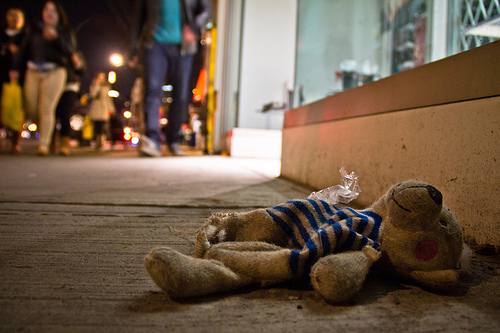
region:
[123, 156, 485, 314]
Teddy bear on the sidewalk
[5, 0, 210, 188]
People walking on the sidewalk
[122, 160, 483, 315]
Ripped teddy bear missing its stuffing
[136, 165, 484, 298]
Teddy bear with blue stripes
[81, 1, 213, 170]
Person wearing blue jeans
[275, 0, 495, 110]
Store front grass window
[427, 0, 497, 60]
Gate across door to a store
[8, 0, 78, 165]
Woman wearing tan colored pants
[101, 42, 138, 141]
Street lights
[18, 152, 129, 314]
Rough concrete sidewalk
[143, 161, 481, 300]
torn apart stuffed bear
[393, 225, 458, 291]
red cheek on stuffed bear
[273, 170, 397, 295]
blue and white shirt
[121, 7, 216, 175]
man walking down the street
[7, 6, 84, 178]
woman carrying a yellow bag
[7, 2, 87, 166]
woman walking down the street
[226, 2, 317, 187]
opening to store entrance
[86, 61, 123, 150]
woman talking on cellphone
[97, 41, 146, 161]
city lights in the distance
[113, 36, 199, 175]
man wearing blue denims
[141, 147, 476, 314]
the teddy bear is flat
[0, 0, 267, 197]
people are walking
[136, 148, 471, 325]
the teddy bear is wearing a blue shirt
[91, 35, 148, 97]
a light is shining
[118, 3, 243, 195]
the person is wearing blue jeans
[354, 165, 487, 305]
the teddy bear has a pink cheek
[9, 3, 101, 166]
the woman is wearing tan pants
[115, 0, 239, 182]
the person is wearing a blue shirt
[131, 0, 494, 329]
a glass window above the bear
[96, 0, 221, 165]
the person is wearing a black jacket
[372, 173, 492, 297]
the head of a teddy bear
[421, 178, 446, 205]
the nose of a teddy bear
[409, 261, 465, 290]
the ear of a teddy bear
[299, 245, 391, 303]
the arm of a teddy bear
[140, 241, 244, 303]
the leg of a teddy bear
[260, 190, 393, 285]
a blue and gray striped shirt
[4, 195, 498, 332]
a gray cement slab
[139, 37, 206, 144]
a pair of blue jeans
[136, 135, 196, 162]
a pair of shoes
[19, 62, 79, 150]
a pair of khaki pants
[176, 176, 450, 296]
brown and blue ripped teddy bear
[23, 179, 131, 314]
brown pavement at night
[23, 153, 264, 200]
brown pavement at night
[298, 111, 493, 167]
brown and red stair at night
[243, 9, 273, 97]
gray side of building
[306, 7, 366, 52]
gray side of building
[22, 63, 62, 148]
woman wearing tan pants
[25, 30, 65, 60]
woman wearing brown sweater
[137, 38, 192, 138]
blue jeans worn by man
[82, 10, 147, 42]
dark blue night sky